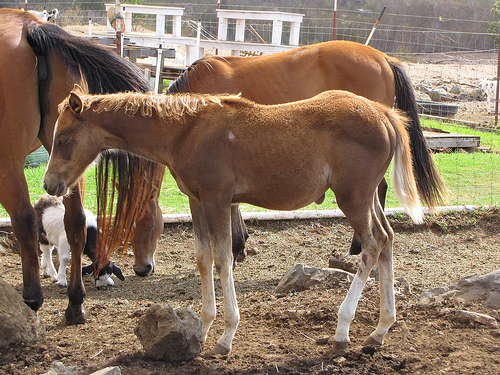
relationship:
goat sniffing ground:
[28, 193, 124, 290] [0, 197, 498, 374]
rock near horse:
[130, 298, 207, 363] [43, 83, 426, 356]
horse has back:
[43, 83, 426, 356] [216, 94, 323, 117]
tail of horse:
[384, 105, 426, 224] [43, 83, 426, 356]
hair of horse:
[81, 88, 246, 116] [60, 70, 425, 352]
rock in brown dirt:
[130, 298, 210, 364] [0, 202, 500, 375]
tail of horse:
[410, 63, 447, 206] [22, 57, 499, 358]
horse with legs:
[38, 80, 433, 362] [195, 241, 397, 352]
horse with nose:
[130, 35, 447, 276] [130, 264, 150, 278]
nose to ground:
[130, 264, 150, 278] [0, 49, 497, 370]